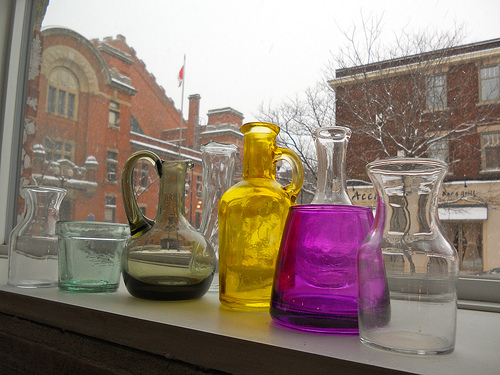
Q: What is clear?
A: Vase.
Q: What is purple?
A: Vase.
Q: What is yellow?
A: Vase.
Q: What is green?
A: Vase.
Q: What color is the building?
A: Red.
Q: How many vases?
A: 8.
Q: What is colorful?
A: Vases.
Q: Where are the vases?
A: Sill.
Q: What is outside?
A: Tree.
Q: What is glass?
A: Vases.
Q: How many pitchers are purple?
A: One.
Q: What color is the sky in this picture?
A: White.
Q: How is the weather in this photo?
A: Overcast.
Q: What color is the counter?
A: Grey.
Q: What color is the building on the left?
A: Red.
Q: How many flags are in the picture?
A: One.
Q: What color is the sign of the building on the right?
A: White.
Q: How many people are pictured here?
A: Zero.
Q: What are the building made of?
A: Brick.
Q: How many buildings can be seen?
A: 3.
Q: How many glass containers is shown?
A: 8.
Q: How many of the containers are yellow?
A: 1.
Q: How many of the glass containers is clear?
A: 5.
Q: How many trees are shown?
A: 2.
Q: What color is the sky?
A: Blue and white.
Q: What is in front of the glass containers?
A: Window.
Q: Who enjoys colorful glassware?
A: The displayer.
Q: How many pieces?
A: 8.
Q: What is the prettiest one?
A: The purple one.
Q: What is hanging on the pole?
A: A flag.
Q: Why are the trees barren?
A: It is winter.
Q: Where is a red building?
A: To the left outside.